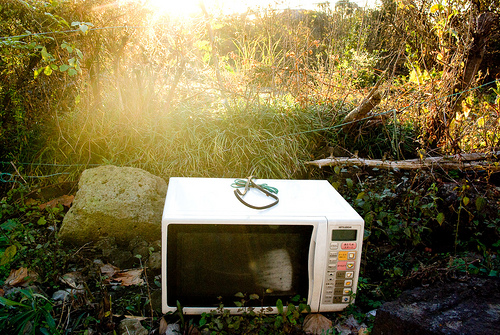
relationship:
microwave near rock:
[157, 171, 362, 312] [60, 166, 165, 242]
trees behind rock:
[2, 1, 499, 334] [60, 166, 165, 242]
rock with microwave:
[60, 166, 165, 242] [157, 171, 362, 312]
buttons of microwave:
[328, 241, 356, 307] [157, 171, 362, 312]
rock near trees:
[60, 166, 165, 242] [2, 1, 499, 334]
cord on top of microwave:
[232, 174, 281, 211] [157, 171, 362, 312]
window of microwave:
[164, 220, 317, 313] [157, 171, 362, 312]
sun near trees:
[110, 0, 379, 33] [2, 1, 499, 334]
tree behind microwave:
[292, 148, 495, 177] [157, 171, 362, 312]